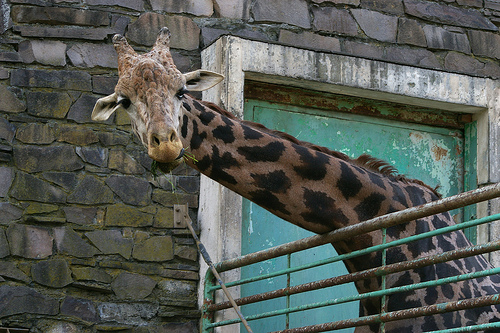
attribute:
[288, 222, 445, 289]
bar — green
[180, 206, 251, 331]
pole — silver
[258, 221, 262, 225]
paint — chipped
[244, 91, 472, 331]
door — faded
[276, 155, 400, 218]
spots — dark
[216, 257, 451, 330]
bars — different colored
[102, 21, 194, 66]
horns — spotted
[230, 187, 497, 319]
gate — rusted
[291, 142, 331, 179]
stripe — black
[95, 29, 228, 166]
head — giraffe's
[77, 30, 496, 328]
giraffe — brown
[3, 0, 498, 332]
wall — stone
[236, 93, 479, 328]
paint — blue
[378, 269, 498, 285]
paint — green